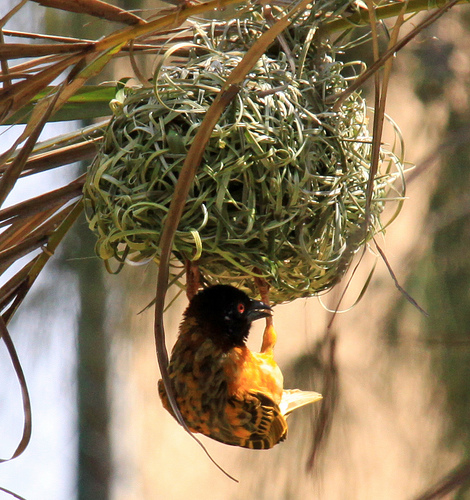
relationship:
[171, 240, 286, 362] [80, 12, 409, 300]
bird has legs legs grip nest bird has a nest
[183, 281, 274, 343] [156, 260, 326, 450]
head is fuzzy head black bird has a head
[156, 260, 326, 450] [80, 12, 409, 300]
bird is hanging bird has a nest nest is hanging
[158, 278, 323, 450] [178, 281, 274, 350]
bird has a head is fuzzy